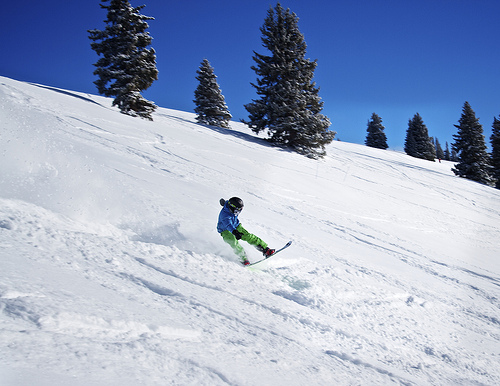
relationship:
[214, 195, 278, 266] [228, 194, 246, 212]
person wearing helmet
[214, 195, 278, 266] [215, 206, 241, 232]
person wearing jacket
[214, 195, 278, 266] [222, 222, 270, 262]
person wearing pants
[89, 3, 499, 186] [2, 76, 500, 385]
trees in snow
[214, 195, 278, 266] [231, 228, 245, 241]
person wearing gloves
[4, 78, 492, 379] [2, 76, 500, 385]
ground has snow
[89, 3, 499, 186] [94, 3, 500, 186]
trees has snow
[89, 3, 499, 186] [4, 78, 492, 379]
trees on ground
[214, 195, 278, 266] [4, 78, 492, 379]
person on ground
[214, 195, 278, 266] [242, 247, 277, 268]
person wearing boots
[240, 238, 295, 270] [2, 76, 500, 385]
snowboard in snow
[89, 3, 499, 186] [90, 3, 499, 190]
trees in line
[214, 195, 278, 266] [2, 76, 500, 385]
person on snow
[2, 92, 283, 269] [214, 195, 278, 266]
snow behind person